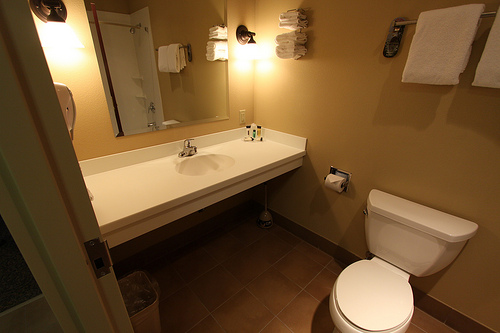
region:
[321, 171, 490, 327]
white toilet in the tan tile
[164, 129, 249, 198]
sink in the counter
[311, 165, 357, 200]
roll of toilet paper folded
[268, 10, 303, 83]
towels on the wall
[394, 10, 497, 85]
towels hanging on the rack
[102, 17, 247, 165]
mirror reflecting shower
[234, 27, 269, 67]
light on wall next to mirror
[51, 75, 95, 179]
soap dispenser on wall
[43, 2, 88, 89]
light on wall next to mirror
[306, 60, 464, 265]
tan color wall behind toilet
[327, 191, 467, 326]
White porcelain toilet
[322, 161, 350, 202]
Toilet paper roll on wall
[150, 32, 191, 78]
Reflection of hanging towels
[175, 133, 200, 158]
Chrome Water faucet for the sink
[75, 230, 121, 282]
Door latch on the door frame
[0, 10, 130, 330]
White Door Frame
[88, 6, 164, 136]
Reflection of the shower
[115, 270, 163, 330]
Garbage can under the sink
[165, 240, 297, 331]
brown tile floors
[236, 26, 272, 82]
light fixture on the wall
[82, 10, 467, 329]
a clean and tidy rest room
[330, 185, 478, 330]
a white toilet with a close lid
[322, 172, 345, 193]
a roll of toilet paper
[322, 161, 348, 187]
toilet paper holder with toilet paper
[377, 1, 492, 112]
towel holder with white towel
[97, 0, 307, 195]
a sink with a large mirror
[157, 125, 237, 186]
a sink with a faucet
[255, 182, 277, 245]
a toilet brush cleaner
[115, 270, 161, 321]
a trash bin with a plastic liner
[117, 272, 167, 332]
an empty trash bin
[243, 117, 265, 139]
Different toiletries on sink counter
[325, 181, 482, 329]
White toilet in bathroom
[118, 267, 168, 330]
Brown bathroom garbage can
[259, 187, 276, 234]
White toilet brush under sink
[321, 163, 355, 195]
A roll of toilet paper in wall holder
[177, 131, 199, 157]
Chrome sink faucet and lever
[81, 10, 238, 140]
Bathroom mirror hanging on yellow wall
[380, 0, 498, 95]
Towel rack with two white towels on it.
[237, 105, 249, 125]
Beige light switch on wall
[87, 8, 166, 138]
Reflection of shower in mirror.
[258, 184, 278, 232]
white toilet brush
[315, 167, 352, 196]
toilet paper on holder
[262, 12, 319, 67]
folded towels on shelf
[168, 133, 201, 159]
silver bathroom faucet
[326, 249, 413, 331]
white bathroom toilet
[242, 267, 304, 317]
tan bathroom tile on floor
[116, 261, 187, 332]
white bathroom trashcan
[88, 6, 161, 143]
reflection of shower in mirror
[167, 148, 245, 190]
white bathroom sink on counter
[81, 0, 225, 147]
large mirror over bathroom counter